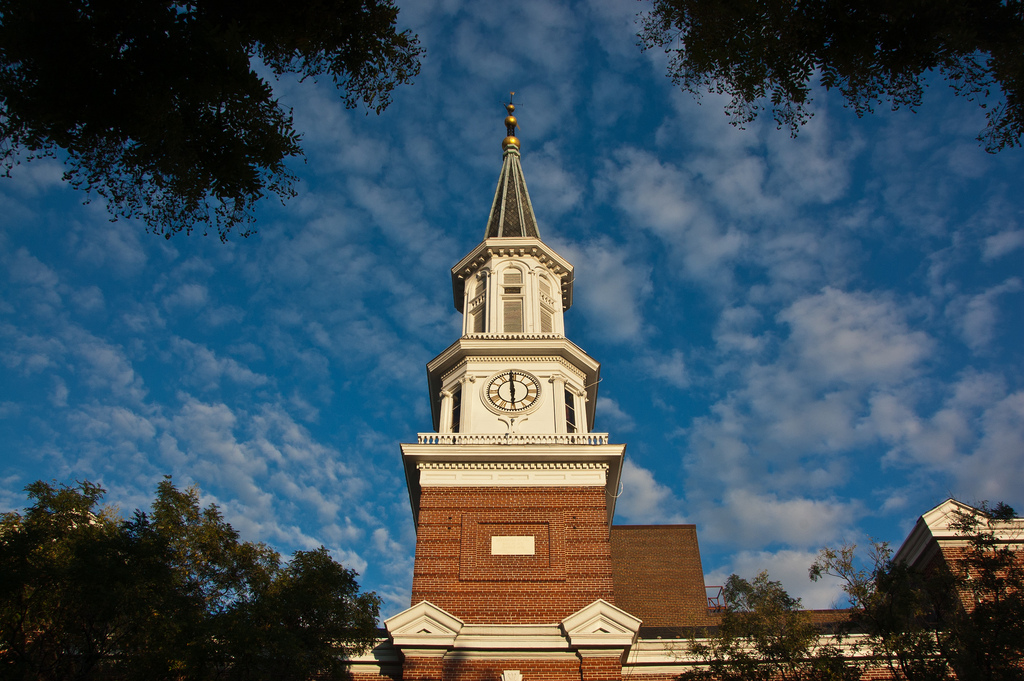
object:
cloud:
[296, 170, 413, 273]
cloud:
[288, 230, 425, 314]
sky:
[0, 0, 1024, 633]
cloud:
[429, 0, 621, 98]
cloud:
[696, 465, 883, 570]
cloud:
[323, 142, 422, 188]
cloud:
[726, 277, 906, 435]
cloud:
[813, 252, 934, 436]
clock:
[479, 367, 547, 418]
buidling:
[381, 106, 644, 681]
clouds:
[24, 230, 245, 384]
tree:
[3, 457, 403, 680]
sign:
[490, 534, 536, 556]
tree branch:
[0, 3, 417, 248]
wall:
[413, 479, 607, 624]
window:
[506, 271, 523, 294]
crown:
[451, 237, 575, 335]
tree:
[682, 571, 843, 681]